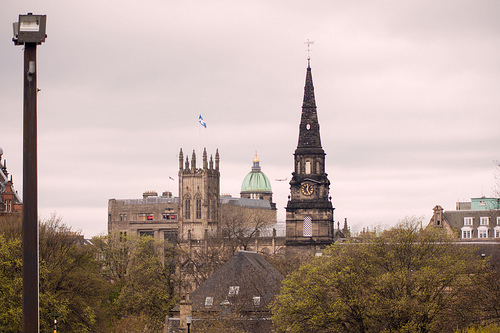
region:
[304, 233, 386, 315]
The tree is green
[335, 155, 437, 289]
The tree is green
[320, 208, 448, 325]
The tree is green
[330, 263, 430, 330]
The tree is green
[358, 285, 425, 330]
The tree is green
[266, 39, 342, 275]
Tall tower with black tiles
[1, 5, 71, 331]
Tall, narrow black light pole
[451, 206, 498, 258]
Building with white windows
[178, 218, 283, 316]
Building with a black roof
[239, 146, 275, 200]
Large blue dome with white top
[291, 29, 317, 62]
Weather vane on top of tower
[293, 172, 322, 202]
Clock is gold and black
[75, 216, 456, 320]
Trees in front of the buildings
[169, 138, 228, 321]
Brown tower with a pointy columns at the top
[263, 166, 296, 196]
A white flying plane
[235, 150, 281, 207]
A green dome on a building.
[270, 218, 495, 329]
Trees in the foreground.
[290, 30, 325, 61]
A cross on top of a building.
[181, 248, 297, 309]
The roof on a building.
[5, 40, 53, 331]
A pole.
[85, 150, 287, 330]
The building is gray.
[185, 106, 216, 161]
A flag on top of the building.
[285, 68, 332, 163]
The top of the building is shaped like a triangle.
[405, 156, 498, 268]
A building in the distance.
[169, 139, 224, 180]
Spires on the top of a building.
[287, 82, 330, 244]
the tower is tall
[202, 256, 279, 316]
the roof is grey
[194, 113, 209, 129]
the flag is blue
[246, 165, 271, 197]
the building is dome shaped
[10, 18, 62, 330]
the pole is tall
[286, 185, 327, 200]
the clock is on the wall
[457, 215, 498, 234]
the windows are six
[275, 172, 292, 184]
the plane is in the sky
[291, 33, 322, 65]
the windvane is on the tower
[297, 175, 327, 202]
the clock says 12.20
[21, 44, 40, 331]
long black round pole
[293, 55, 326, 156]
tall dark triangular steeple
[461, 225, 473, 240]
small double pane window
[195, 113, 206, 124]
small white and blue flag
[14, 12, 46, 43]
single black and clear light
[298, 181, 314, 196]
small black white clock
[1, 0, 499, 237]
dark and stormy sky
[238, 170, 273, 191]
light colored round top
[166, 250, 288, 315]
black and brown roof top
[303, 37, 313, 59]
a small silver weather vein